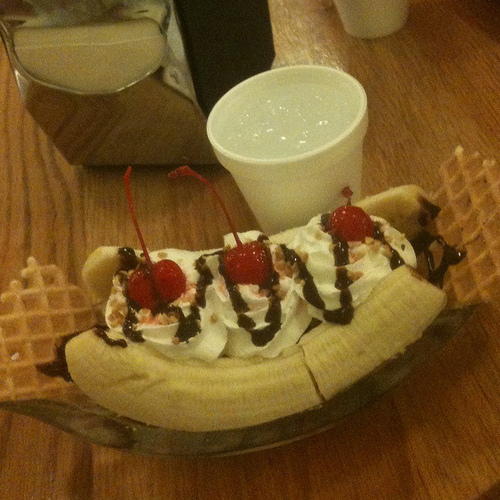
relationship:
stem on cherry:
[120, 164, 158, 272] [123, 163, 189, 305]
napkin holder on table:
[0, 0, 275, 172] [0, 0, 499, 499]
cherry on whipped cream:
[123, 163, 189, 305] [101, 208, 415, 362]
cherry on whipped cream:
[166, 162, 274, 285] [101, 208, 415, 362]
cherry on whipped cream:
[326, 184, 375, 243] [101, 208, 415, 362]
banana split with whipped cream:
[0, 143, 499, 456] [101, 208, 415, 362]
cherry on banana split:
[123, 163, 189, 305] [0, 143, 499, 456]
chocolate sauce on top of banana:
[37, 196, 466, 382] [64, 262, 446, 435]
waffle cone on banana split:
[0, 254, 117, 415] [0, 143, 499, 456]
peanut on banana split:
[277, 287, 290, 301] [0, 143, 499, 456]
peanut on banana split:
[211, 308, 221, 323] [0, 143, 499, 456]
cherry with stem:
[123, 163, 189, 305] [120, 164, 158, 272]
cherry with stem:
[166, 162, 274, 285] [166, 163, 249, 248]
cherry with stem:
[326, 184, 375, 243] [340, 183, 358, 207]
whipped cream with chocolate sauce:
[101, 208, 415, 362] [37, 196, 466, 382]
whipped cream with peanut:
[101, 208, 415, 362] [277, 287, 290, 301]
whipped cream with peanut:
[101, 208, 415, 362] [211, 308, 221, 323]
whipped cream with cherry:
[101, 208, 415, 362] [123, 163, 189, 305]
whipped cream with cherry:
[101, 208, 415, 362] [166, 162, 274, 285]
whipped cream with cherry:
[101, 208, 415, 362] [326, 184, 375, 243]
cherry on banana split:
[166, 162, 274, 285] [0, 143, 499, 456]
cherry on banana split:
[326, 184, 375, 243] [0, 143, 499, 456]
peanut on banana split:
[170, 335, 185, 344] [0, 143, 499, 456]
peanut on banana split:
[364, 234, 376, 246] [0, 143, 499, 456]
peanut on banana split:
[344, 269, 362, 281] [0, 143, 499, 456]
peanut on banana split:
[158, 251, 172, 260] [0, 143, 499, 456]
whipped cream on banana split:
[101, 208, 415, 362] [0, 143, 499, 456]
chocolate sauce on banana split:
[37, 196, 466, 382] [0, 143, 499, 456]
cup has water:
[205, 62, 369, 234] [212, 64, 361, 159]